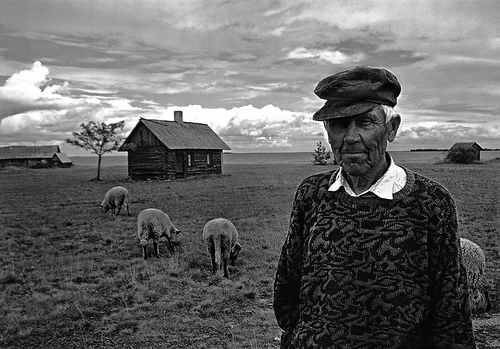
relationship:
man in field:
[274, 51, 461, 343] [3, 150, 484, 347]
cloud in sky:
[0, 59, 95, 107] [3, 0, 483, 156]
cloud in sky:
[201, 90, 308, 139] [3, 0, 483, 156]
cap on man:
[311, 67, 400, 121] [253, 61, 478, 346]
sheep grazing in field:
[458, 238, 493, 320] [3, 150, 484, 347]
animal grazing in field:
[201, 216, 242, 276] [3, 150, 484, 347]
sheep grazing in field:
[137, 209, 183, 260] [3, 150, 484, 347]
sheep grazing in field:
[97, 186, 131, 216] [3, 150, 484, 347]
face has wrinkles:
[318, 103, 401, 187] [371, 115, 388, 160]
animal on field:
[201, 215, 246, 277] [3, 150, 484, 347]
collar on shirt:
[325, 153, 398, 200] [329, 155, 409, 202]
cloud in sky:
[157, 6, 295, 112] [3, 0, 483, 156]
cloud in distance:
[0, 59, 95, 107] [3, 5, 482, 162]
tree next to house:
[62, 113, 135, 187] [118, 106, 232, 179]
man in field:
[274, 65, 475, 347] [8, 142, 434, 346]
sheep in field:
[458, 238, 493, 320] [1, 127, 497, 347]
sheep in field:
[97, 177, 132, 212] [1, 127, 497, 347]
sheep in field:
[134, 202, 184, 260] [1, 127, 497, 347]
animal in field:
[201, 216, 242, 276] [1, 127, 497, 347]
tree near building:
[64, 119, 137, 179] [118, 110, 229, 183]